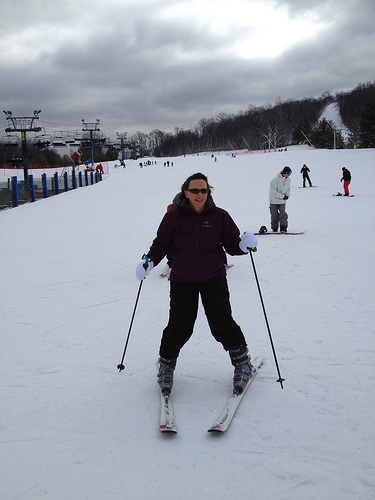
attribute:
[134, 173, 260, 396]
skier — woman, skiing, happy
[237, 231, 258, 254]
glove — white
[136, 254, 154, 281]
glove — white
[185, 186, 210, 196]
sunglasses — dark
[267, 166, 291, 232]
skier — skiing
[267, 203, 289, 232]
pants — gray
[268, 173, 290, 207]
jacket — white, red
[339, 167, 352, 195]
skier — skiing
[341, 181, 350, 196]
pants — red, snow pants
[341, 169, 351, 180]
jacket — dark, black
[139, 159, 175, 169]
skiers — skiing, having fun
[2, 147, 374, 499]
slope — snow covered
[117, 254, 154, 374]
ski pole — black, dark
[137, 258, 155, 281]
hand — gloved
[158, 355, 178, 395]
ski boot — gray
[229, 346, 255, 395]
ski boot — gray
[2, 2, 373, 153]
sky — cloudy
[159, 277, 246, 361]
pants — black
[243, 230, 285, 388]
ski pole — dark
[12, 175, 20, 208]
post — blue, metal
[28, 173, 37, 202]
post — blue, metal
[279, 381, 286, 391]
point — sharp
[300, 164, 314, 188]
person — snowboarding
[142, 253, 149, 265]
strap — green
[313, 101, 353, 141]
snow — white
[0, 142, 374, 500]
snow — white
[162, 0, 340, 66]
clouds — white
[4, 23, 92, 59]
clouds — white